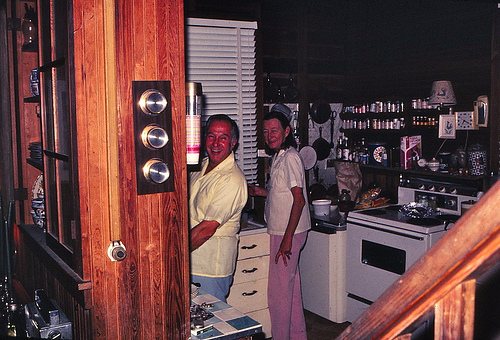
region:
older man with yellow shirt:
[183, 112, 245, 285]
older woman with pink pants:
[260, 107, 335, 338]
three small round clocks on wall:
[134, 38, 172, 186]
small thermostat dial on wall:
[97, 242, 144, 286]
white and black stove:
[309, 173, 438, 326]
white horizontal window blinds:
[200, 16, 264, 97]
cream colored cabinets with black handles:
[245, 214, 257, 311]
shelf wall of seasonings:
[353, 88, 464, 193]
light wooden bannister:
[362, 240, 495, 269]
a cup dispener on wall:
[183, 81, 212, 190]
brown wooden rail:
[313, 180, 499, 331]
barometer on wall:
[131, 72, 174, 198]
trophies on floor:
[0, 240, 77, 338]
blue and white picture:
[435, 111, 465, 146]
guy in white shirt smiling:
[190, 102, 248, 289]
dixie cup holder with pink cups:
[186, 71, 210, 169]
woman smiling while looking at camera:
[256, 111, 315, 336]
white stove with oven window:
[336, 185, 475, 332]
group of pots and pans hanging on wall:
[292, 91, 345, 173]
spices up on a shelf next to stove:
[340, 88, 446, 138]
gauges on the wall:
[120, 67, 184, 212]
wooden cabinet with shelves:
[4, 0, 197, 334]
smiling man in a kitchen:
[191, 100, 248, 327]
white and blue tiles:
[183, 272, 278, 337]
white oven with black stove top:
[333, 162, 498, 336]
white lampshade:
[425, 77, 464, 123]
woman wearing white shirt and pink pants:
[244, 95, 324, 339]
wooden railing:
[313, 107, 498, 339]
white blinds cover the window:
[187, 12, 282, 223]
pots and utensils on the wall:
[299, 93, 351, 192]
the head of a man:
[198, 107, 245, 166]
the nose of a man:
[209, 133, 221, 149]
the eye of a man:
[217, 132, 230, 143]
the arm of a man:
[189, 177, 247, 253]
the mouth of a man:
[206, 143, 224, 156]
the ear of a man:
[229, 133, 243, 149]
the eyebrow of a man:
[219, 129, 234, 140]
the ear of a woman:
[281, 120, 294, 137]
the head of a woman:
[254, 108, 297, 158]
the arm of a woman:
[276, 149, 308, 239]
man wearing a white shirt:
[189, 107, 244, 297]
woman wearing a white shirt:
[243, 108, 330, 275]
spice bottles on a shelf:
[333, 92, 413, 134]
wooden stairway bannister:
[372, 201, 482, 336]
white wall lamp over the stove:
[425, 70, 465, 125]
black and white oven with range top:
[340, 168, 452, 279]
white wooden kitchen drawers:
[228, 226, 271, 326]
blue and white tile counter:
[193, 287, 266, 338]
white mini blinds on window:
[191, 19, 261, 96]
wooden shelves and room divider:
[18, 28, 128, 235]